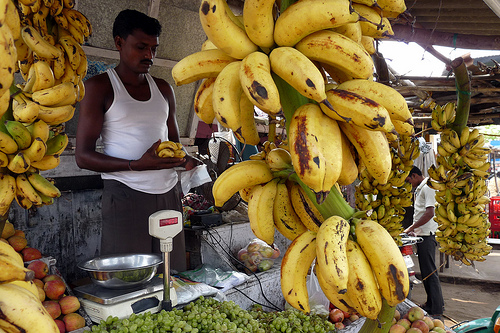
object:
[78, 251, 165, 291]
bowl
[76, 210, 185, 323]
scale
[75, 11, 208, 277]
man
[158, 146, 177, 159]
bananas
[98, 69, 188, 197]
mans shirt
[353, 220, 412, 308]
bananas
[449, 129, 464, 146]
fruit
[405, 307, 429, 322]
apples